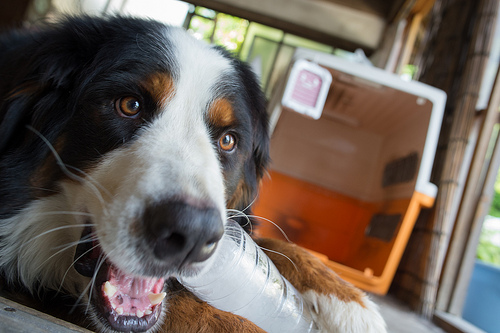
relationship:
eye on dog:
[218, 120, 243, 166] [4, 10, 389, 331]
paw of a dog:
[301, 265, 392, 332] [4, 10, 389, 331]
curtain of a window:
[414, 7, 498, 313] [431, 132, 498, 328]